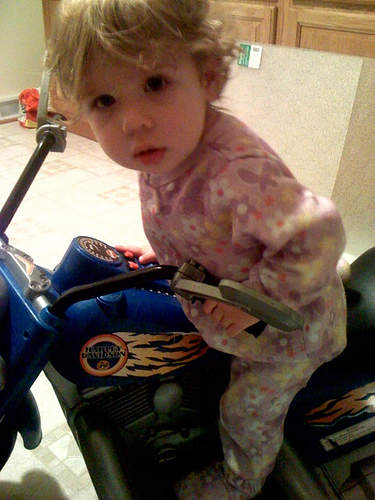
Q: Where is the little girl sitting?
A: On the bike seat.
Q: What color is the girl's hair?
A: Blonde.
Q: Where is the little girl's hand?
A: On the bike handlebar.